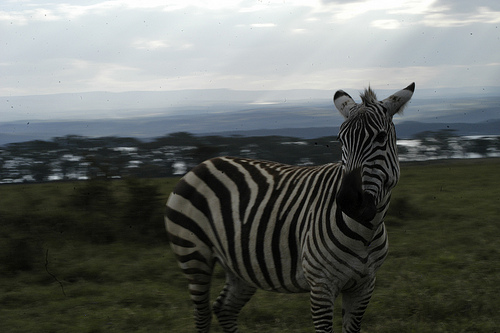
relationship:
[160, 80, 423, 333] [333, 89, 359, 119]
zebra has ear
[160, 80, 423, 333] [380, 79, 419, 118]
zebra has ear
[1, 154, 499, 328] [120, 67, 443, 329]
grass under animal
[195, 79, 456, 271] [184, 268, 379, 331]
zebra has legs